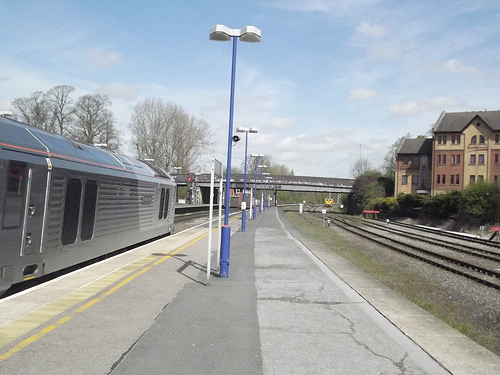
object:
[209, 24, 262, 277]
street light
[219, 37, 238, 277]
pole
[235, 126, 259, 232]
street light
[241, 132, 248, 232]
pole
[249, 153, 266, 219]
street light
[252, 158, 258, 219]
pole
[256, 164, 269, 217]
street light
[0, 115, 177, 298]
train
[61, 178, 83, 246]
window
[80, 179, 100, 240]
window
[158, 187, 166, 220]
window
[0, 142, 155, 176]
stripe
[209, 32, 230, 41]
light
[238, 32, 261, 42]
light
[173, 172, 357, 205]
bridge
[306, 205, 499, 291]
tracks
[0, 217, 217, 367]
line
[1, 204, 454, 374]
platform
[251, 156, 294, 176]
trees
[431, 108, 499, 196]
building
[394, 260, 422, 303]
gravel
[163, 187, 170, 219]
window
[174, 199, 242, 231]
tracks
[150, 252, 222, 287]
shadow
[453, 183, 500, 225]
bush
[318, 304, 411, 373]
crack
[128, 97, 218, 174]
trees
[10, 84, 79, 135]
trees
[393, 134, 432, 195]
building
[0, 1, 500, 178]
sky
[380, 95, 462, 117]
cloud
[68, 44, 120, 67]
cloud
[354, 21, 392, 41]
cloud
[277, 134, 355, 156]
cloud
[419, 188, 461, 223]
bush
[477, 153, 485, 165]
window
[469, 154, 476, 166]
window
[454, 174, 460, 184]
window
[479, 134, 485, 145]
window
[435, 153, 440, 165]
window